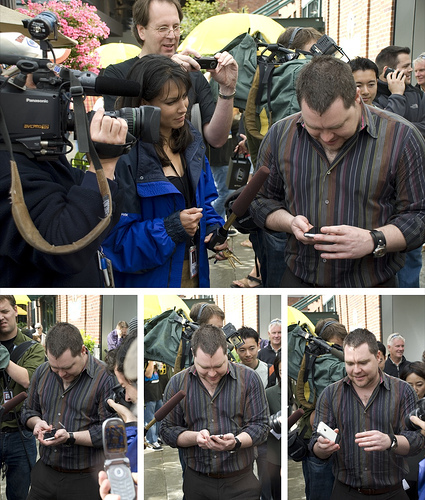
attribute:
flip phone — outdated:
[102, 414, 137, 499]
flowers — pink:
[54, 8, 126, 94]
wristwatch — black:
[373, 226, 391, 261]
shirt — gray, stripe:
[254, 109, 421, 258]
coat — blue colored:
[97, 141, 231, 288]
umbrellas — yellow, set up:
[89, 11, 286, 68]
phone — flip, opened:
[296, 211, 323, 242]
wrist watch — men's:
[368, 226, 388, 259]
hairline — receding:
[193, 345, 234, 354]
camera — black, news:
[0, 13, 167, 164]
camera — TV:
[22, 57, 136, 140]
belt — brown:
[339, 480, 400, 493]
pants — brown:
[331, 482, 410, 498]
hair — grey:
[267, 321, 276, 327]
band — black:
[387, 431, 400, 448]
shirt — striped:
[244, 101, 423, 283]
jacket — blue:
[112, 405, 127, 438]